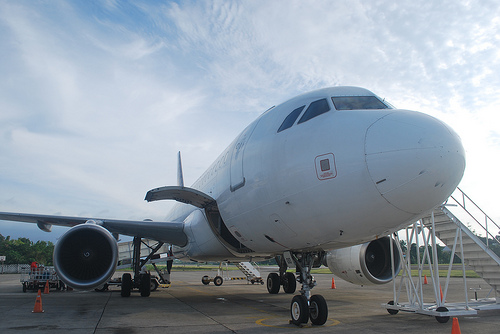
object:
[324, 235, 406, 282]
jet engine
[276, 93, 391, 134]
cockpit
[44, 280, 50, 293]
traffic cone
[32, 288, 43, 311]
traffic cone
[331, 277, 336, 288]
traffic cone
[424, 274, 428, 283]
traffic cone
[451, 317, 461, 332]
traffic cone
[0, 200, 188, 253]
wing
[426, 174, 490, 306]
stairs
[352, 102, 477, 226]
nose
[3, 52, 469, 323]
plane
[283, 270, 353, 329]
tyre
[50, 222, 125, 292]
engine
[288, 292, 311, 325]
tire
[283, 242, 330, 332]
landing gear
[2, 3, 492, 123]
sky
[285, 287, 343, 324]
wheels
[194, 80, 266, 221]
door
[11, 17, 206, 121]
clouds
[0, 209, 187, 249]
right wing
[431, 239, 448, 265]
trees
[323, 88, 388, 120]
window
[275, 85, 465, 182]
windshield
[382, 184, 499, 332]
portable staircase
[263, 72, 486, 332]
front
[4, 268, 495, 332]
land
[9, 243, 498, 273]
distance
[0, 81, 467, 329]
jet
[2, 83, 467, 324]
airplane